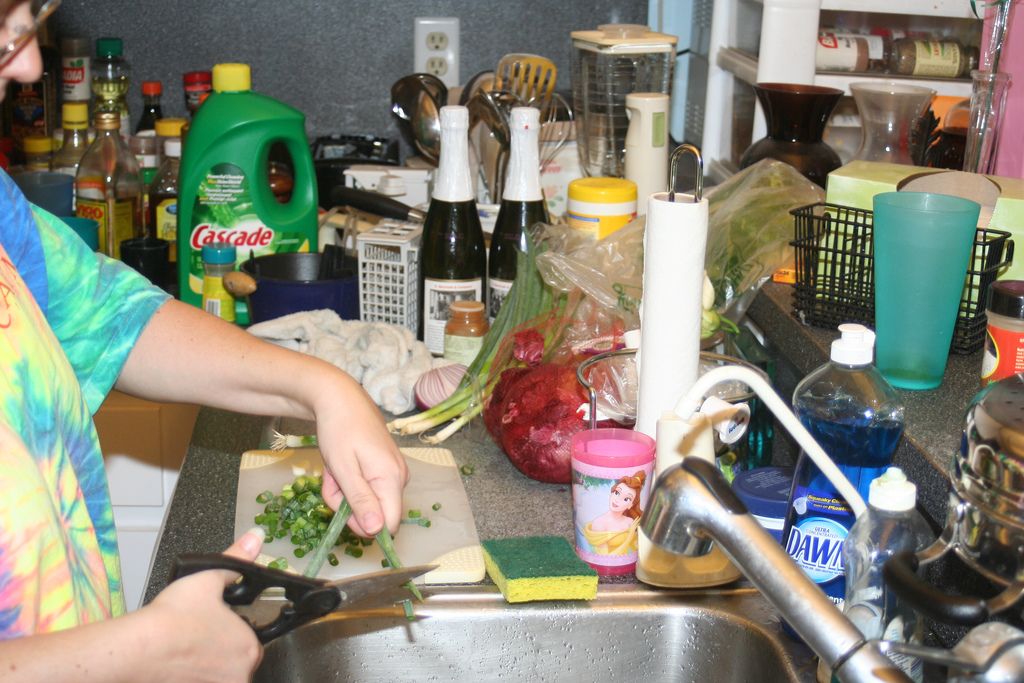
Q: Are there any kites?
A: No, there are no kites.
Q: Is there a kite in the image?
A: No, there are no kites.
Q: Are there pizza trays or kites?
A: No, there are no kites or pizza trays.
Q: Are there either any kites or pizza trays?
A: No, there are no kites or pizza trays.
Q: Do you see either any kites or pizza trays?
A: No, there are no kites or pizza trays.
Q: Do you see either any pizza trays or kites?
A: No, there are no kites or pizza trays.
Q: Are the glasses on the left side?
A: Yes, the glasses are on the left of the image.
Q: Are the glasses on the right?
A: No, the glasses are on the left of the image.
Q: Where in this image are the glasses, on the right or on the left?
A: The glasses are on the left of the image.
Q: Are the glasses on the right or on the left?
A: The glasses are on the left of the image.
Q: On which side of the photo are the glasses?
A: The glasses are on the left of the image.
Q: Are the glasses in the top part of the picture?
A: Yes, the glasses are in the top of the image.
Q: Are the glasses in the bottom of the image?
A: No, the glasses are in the top of the image.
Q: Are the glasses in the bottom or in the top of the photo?
A: The glasses are in the top of the image.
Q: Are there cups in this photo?
A: Yes, there is a cup.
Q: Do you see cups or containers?
A: Yes, there is a cup.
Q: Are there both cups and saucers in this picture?
A: No, there is a cup but no saucers.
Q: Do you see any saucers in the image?
A: No, there are no saucers.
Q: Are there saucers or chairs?
A: No, there are no saucers or chairs.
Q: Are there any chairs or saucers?
A: No, there are no saucers or chairs.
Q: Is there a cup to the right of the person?
A: Yes, there is a cup to the right of the person.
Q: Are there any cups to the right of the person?
A: Yes, there is a cup to the right of the person.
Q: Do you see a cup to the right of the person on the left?
A: Yes, there is a cup to the right of the person.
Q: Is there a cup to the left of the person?
A: No, the cup is to the right of the person.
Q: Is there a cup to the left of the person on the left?
A: No, the cup is to the right of the person.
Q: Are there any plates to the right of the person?
A: No, there is a cup to the right of the person.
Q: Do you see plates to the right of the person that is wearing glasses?
A: No, there is a cup to the right of the person.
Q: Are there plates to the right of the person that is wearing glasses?
A: No, there is a cup to the right of the person.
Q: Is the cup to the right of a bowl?
A: No, the cup is to the right of a person.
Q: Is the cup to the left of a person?
A: No, the cup is to the right of a person.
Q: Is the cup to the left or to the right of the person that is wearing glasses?
A: The cup is to the right of the person.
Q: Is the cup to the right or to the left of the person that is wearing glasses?
A: The cup is to the right of the person.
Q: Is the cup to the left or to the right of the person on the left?
A: The cup is to the right of the person.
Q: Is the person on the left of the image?
A: Yes, the person is on the left of the image.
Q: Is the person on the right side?
A: No, the person is on the left of the image.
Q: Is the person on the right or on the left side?
A: The person is on the left of the image.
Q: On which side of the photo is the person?
A: The person is on the left of the image.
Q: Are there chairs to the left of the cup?
A: No, there is a person to the left of the cup.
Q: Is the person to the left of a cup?
A: Yes, the person is to the left of a cup.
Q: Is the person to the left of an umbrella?
A: No, the person is to the left of a cup.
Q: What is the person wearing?
A: The person is wearing glasses.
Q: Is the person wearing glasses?
A: Yes, the person is wearing glasses.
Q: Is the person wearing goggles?
A: No, the person is wearing glasses.